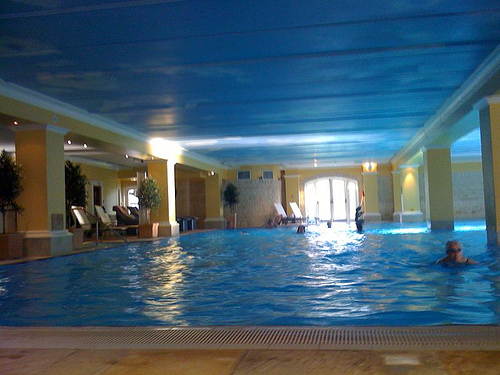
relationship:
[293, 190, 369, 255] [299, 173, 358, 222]
sunshine shining through doors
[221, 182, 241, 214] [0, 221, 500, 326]
plant lining side of pool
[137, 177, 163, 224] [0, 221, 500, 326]
plant lining side of pool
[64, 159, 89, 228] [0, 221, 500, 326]
plant lining side of pool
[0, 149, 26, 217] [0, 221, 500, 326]
plant lining side of pool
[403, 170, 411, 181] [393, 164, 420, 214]
fixture on wall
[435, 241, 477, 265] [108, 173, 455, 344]
person swimming in pool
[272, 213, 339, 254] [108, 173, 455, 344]
person swimming in pool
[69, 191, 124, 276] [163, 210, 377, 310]
chair on side of pool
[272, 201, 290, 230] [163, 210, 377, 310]
chair on side of pool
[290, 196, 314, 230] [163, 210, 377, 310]
chair on side of pool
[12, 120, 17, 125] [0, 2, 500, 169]
lighting in ceiling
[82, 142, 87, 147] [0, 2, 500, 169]
lighting in ceiling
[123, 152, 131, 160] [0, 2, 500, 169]
lighting in ceiling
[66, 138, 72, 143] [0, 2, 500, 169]
lighting in ceiling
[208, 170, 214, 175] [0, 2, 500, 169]
lighting in ceiling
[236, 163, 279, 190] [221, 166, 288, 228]
vents in wall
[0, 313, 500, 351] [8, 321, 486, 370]
drain on border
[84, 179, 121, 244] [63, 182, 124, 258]
doorway behind chair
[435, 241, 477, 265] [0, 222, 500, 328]
person swimming in pool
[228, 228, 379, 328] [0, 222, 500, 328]
water in pool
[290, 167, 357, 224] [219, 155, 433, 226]
doors on wall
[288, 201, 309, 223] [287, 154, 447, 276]
chair beside door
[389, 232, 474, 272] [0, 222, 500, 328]
person in pool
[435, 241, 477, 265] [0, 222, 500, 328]
person in pool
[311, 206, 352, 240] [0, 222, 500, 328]
person in pool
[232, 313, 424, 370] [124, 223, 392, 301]
drain by pool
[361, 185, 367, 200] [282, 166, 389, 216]
red item hanging on wall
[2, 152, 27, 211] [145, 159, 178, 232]
plant next to column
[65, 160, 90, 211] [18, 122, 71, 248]
plant next to column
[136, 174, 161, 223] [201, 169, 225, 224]
plant next to column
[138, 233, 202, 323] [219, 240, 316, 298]
light on water